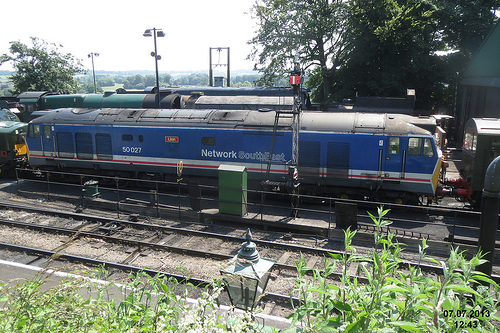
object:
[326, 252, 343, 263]
leaves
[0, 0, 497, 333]
station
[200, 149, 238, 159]
name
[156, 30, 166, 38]
light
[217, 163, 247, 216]
box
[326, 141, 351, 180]
door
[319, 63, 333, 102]
trunk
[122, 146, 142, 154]
writing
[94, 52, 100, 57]
streetlight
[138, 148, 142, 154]
numbers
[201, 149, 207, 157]
letters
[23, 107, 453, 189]
train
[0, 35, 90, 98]
tree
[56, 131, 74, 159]
window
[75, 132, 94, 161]
window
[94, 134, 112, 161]
window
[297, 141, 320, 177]
window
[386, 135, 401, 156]
window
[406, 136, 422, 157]
window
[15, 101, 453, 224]
train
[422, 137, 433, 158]
window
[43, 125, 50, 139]
window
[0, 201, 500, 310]
rails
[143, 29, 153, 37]
light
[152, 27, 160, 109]
pole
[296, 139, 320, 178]
door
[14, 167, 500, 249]
fence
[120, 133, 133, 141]
windows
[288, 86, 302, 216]
pole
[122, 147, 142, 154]
50027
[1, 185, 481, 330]
rail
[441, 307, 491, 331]
date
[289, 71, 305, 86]
light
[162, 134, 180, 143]
sign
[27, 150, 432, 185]
line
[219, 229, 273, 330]
light post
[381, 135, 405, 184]
train door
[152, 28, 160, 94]
lamp post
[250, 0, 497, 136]
tree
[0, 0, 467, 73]
sky